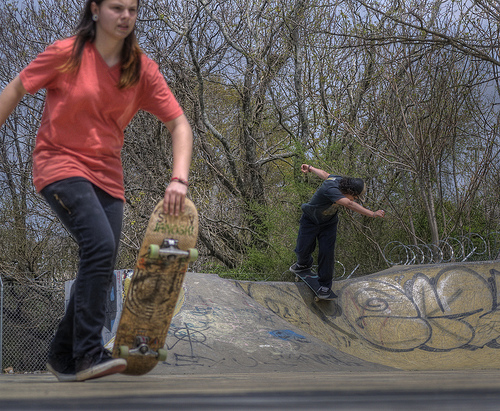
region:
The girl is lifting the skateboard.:
[72, 3, 222, 359]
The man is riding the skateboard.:
[298, 160, 388, 349]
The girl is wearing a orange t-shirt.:
[44, 31, 159, 202]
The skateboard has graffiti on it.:
[137, 210, 192, 345]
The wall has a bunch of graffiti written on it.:
[179, 280, 497, 365]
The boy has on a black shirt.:
[311, 174, 361, 235]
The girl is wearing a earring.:
[88, 4, 112, 31]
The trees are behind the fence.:
[222, 10, 479, 242]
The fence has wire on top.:
[356, 225, 495, 269]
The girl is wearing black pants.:
[8, 160, 121, 379]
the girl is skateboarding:
[0, 0, 198, 383]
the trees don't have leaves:
[1, 0, 496, 369]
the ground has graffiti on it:
[163, 272, 498, 367]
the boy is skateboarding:
[290, 162, 382, 302]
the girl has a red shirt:
[19, 37, 183, 199]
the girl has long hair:
[68, 0, 148, 86]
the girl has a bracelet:
[170, 176, 188, 185]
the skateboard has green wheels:
[118, 245, 198, 355]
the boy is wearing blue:
[297, 173, 347, 287]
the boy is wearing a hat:
[346, 175, 368, 199]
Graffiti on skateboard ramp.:
[53, 250, 498, 395]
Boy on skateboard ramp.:
[279, 145, 405, 333]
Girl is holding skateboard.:
[0, 2, 207, 384]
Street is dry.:
[1, 378, 496, 409]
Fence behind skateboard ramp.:
[2, 225, 498, 388]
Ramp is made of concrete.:
[58, 252, 498, 393]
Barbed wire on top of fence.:
[295, 229, 496, 289]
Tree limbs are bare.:
[7, 2, 497, 362]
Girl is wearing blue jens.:
[4, 0, 209, 386]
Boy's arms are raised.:
[280, 157, 393, 304]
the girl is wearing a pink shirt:
[17, 31, 182, 201]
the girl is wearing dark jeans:
[32, 173, 127, 363]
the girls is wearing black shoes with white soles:
[47, 344, 126, 386]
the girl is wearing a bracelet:
[164, 171, 191, 187]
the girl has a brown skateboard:
[102, 193, 208, 381]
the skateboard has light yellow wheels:
[116, 242, 199, 367]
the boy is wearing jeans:
[296, 212, 338, 286]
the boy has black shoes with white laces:
[285, 258, 334, 305]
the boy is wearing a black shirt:
[293, 169, 348, 221]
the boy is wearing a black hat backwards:
[340, 174, 366, 199]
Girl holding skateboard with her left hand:
[0, 6, 220, 393]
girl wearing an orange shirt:
[4, 7, 225, 385]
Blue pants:
[30, 170, 134, 364]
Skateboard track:
[10, 254, 498, 406]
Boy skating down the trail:
[287, 154, 388, 324]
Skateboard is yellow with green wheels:
[98, 180, 212, 385]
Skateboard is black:
[277, 252, 341, 312]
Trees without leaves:
[4, 4, 496, 254]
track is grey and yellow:
[2, 258, 496, 402]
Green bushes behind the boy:
[222, 134, 496, 278]